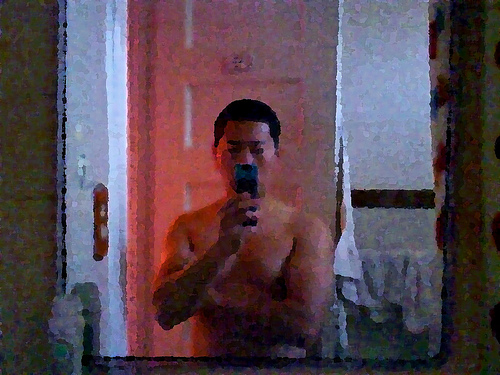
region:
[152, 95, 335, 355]
man taking a selfie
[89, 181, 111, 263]
wood outlet cover with two plugs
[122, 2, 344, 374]
closed white wood door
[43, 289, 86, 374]
white and green container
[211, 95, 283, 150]
short black hair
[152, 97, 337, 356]
man holding a cellphone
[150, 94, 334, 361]
man with no clothing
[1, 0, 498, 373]
shot has blurry special effect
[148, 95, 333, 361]
person is shooting selfie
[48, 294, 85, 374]
plastic bottle against mirror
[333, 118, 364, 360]
shirt hanging on back of door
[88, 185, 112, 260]
red box reflected in mirror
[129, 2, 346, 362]
door behind person in mirror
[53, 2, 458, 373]
blue rim on mirror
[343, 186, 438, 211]
wood trim on wall in mirror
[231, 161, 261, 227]
person is holding cell phone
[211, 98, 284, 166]
person has black hair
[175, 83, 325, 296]
man is taking selfie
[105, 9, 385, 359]
door behind the man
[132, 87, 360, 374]
This is a person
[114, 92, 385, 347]
this is a man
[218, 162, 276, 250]
this is a phone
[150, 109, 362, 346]
the man is taking a selfie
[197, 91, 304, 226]
the head of a man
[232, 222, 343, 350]
the hand of a man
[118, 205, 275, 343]
the hand of a man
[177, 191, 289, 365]
the body of a man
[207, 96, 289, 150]
the hair is black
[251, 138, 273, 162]
the eye of a man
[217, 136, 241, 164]
the eye of a man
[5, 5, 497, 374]
photo with filter applied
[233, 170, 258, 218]
black cell phone in mans hand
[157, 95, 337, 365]
shirtless man taking mirror selfie